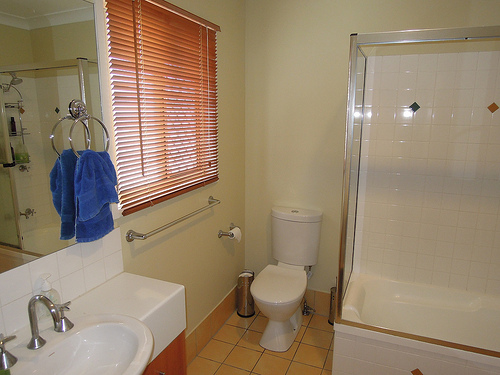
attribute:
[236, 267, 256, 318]
trash can — silver, metal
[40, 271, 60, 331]
dispenser — soap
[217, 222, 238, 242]
holder — silver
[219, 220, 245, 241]
dispenser — silver, metal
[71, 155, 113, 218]
towel — blue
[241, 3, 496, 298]
wall — white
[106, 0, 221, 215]
window blind — brown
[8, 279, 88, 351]
faucet — silver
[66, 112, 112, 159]
towel ring — metal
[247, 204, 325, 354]
toilet — porcelain, white, small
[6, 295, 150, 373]
sink — metal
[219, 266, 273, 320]
container — small, metal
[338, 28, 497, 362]
door — glass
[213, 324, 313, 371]
pattern — diamond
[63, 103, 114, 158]
rack — metal, towel